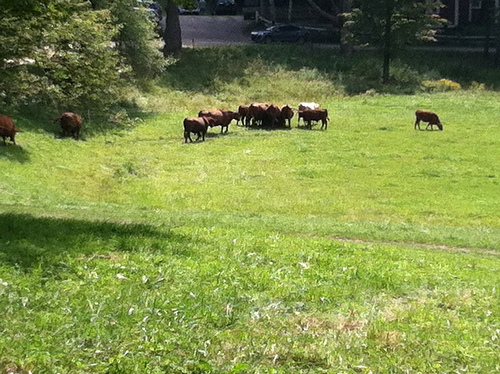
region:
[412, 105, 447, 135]
Brown cow grazing on grass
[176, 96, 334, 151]
Grouping of cows grazing in a grassy field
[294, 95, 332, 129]
Brown cow and a white cow grazing next to each other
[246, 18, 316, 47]
A silver/blue four door sedan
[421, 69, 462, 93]
Group of yellow flowers and weeds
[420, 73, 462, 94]
Group of weeds with yellow flowers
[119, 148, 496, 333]
Pasture of yellow-green grass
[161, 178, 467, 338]
Pasture of green-yellow grass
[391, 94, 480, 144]
Brown cow grazing on green grass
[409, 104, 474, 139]
A brown cow grazing in a pasture of green grass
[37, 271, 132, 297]
short yellow and green grass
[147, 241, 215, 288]
short yellow and green grass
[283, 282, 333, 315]
short yellow and green grass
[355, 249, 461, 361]
short yellow and green grass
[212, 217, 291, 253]
short yellow and green grass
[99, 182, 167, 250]
short yellow and green grass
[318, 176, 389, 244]
short yellow and green grass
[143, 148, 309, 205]
short yellow and green grass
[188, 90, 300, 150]
brown cows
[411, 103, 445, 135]
brown cow in a green field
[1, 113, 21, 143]
brown cow in a green field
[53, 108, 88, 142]
brown cow in a green field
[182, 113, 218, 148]
brown cow in a green field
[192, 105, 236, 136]
brown cow in a green field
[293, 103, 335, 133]
brown cow in a green field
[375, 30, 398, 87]
trunk of a tree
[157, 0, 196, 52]
trunk of a tree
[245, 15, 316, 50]
car parked behind the field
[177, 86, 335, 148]
group of cows in the field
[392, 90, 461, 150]
this is a cow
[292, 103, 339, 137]
this is a cow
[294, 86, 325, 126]
this is a cow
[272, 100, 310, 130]
this is a cow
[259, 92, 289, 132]
this is a cow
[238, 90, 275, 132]
this is a cow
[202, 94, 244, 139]
this is a cow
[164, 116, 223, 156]
this is a cow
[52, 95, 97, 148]
this is a cow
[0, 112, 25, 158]
this is a cow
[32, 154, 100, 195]
short green and yellow grass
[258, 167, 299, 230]
short green and yellow grass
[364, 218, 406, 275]
short green and yellow grass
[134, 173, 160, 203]
short green and yellow grass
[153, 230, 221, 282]
short green and yellow grass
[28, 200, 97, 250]
short green and yellow grass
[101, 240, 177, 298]
short green and yellow grass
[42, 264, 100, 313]
short green and yellow grass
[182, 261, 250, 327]
short green and yellow grass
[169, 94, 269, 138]
brown cows